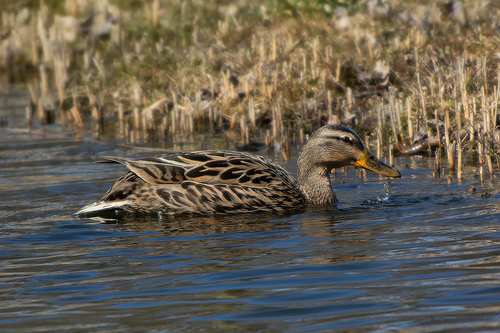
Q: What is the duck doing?
A: Swimming.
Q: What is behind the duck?
A: Dead grass.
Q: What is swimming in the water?
A: A duck.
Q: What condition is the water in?
A: Calm.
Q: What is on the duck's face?
A: A bill.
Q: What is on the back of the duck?
A: Feathers.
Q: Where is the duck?
A: In the water.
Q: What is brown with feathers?
A: The duck.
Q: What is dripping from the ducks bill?
A: Water.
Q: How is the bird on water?
A: Floating.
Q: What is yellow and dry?
A: Grass.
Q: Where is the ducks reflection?
A: Water.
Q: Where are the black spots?
A: On feathers.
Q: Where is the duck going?
A: To the shrubs.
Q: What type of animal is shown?
A: Duck.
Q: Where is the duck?
A: In the water.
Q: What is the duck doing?
A: Swimming.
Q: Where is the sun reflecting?
A: Water.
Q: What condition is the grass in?
A: Brown.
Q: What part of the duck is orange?
A: The beak.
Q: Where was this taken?
A: At a lake.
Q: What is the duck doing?
A: Swimming.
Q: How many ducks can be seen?
A: One.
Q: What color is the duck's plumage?
A: Brown and black.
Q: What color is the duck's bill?
A: Yellow.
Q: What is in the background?
A: Grass.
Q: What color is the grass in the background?
A: Golden brown.